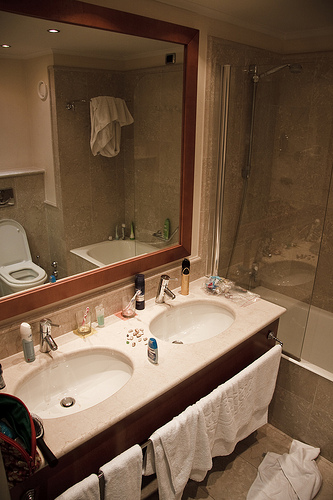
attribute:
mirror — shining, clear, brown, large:
[84, 12, 196, 267]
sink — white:
[156, 298, 227, 353]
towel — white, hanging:
[93, 92, 130, 169]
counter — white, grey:
[161, 347, 188, 381]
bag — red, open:
[6, 408, 44, 463]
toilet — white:
[6, 225, 42, 283]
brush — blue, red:
[125, 293, 150, 308]